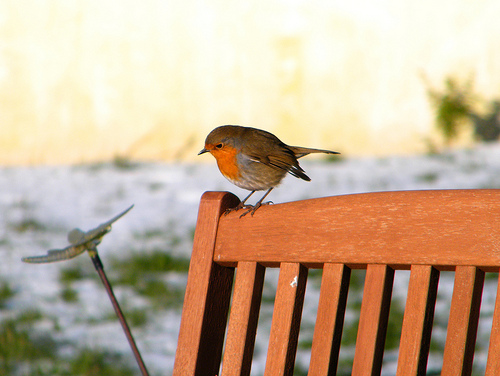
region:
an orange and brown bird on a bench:
[196, 123, 341, 213]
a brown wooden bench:
[168, 189, 498, 374]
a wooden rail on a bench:
[266, 260, 303, 374]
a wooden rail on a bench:
[306, 263, 350, 374]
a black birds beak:
[198, 145, 208, 158]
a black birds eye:
[216, 142, 223, 149]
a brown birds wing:
[245, 128, 310, 183]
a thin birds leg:
[258, 187, 276, 206]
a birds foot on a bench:
[236, 200, 272, 215]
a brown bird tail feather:
[290, 148, 340, 162]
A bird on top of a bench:
[194, 118, 314, 233]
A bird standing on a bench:
[191, 118, 329, 218]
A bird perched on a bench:
[194, 115, 332, 229]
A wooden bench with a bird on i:
[180, 184, 498, 366]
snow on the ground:
[28, 163, 182, 370]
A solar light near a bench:
[37, 203, 159, 373]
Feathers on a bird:
[238, 121, 282, 185]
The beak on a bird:
[195, 143, 207, 157]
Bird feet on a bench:
[232, 188, 274, 220]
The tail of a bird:
[285, 135, 359, 179]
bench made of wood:
[193, 192, 474, 368]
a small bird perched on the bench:
[192, 105, 333, 260]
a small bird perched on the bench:
[182, 117, 300, 222]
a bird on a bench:
[151, 80, 406, 290]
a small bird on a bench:
[144, 81, 416, 273]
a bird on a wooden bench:
[148, 75, 405, 298]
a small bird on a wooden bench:
[150, 70, 489, 362]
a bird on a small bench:
[158, 109, 333, 243]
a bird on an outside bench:
[130, 25, 450, 365]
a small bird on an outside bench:
[42, 91, 476, 366]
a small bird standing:
[182, 56, 439, 369]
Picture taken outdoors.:
[21, 16, 497, 343]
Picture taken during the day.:
[26, 25, 486, 354]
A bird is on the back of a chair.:
[188, 189, 480, 375]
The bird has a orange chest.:
[218, 153, 235, 176]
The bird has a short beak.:
[193, 131, 205, 157]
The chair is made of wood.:
[183, 182, 494, 348]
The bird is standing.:
[198, 110, 300, 225]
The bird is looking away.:
[230, 140, 306, 205]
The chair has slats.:
[217, 263, 439, 358]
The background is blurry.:
[64, 52, 161, 194]